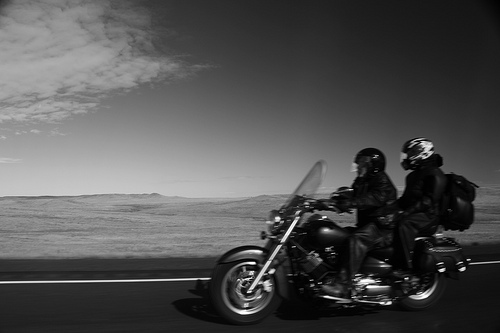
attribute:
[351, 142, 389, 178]
helmet — black, white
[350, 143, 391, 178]
head — person's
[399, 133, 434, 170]
helmet — white, black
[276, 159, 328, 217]
windshield — small, motorcycle's, tall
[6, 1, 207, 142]
clouds — white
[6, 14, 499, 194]
sky — dark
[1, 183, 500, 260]
plains — sandy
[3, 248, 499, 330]
road — paved, black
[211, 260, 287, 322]
tire — black, rubber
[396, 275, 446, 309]
tire — rubber, black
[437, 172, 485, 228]
backpack — large, black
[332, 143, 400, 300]
driver — male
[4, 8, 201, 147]
cloud — large, white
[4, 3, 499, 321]
picture — colorless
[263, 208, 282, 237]
headlight — round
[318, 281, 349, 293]
boots — black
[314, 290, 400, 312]
pipe — chrome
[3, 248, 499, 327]
pavement — black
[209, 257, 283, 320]
front wheel — black, round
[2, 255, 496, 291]
stripe — white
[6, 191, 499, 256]
mountain — brown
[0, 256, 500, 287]
line — white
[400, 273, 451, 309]
back wheel — black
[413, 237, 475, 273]
saddle bag — black